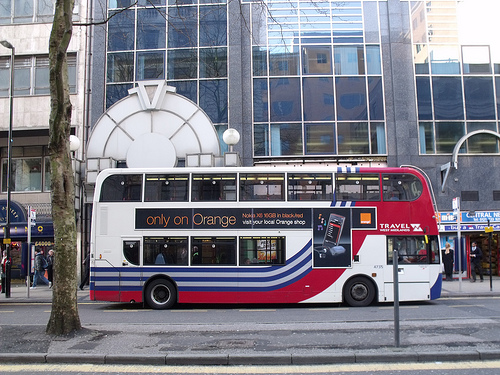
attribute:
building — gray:
[87, 0, 498, 169]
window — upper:
[143, 171, 190, 202]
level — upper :
[91, 166, 433, 202]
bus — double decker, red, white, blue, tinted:
[89, 166, 444, 305]